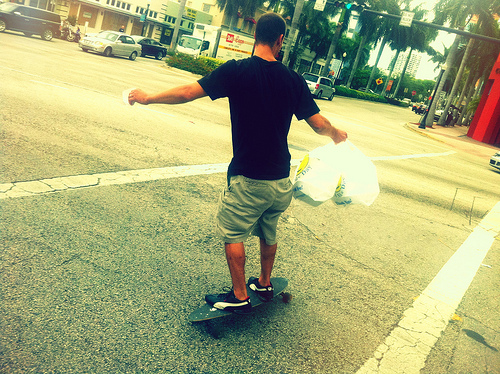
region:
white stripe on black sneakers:
[208, 292, 262, 312]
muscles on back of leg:
[217, 236, 258, 263]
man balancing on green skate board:
[177, 260, 302, 329]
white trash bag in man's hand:
[289, 119, 414, 228]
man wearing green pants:
[201, 158, 297, 257]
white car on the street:
[86, 26, 155, 56]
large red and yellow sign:
[371, 71, 392, 87]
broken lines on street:
[375, 327, 426, 349]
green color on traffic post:
[334, 1, 356, 16]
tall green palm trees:
[331, 5, 396, 117]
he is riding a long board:
[106, 2, 456, 372]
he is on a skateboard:
[96, 4, 428, 361]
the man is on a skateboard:
[96, 7, 443, 369]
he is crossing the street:
[96, 3, 423, 353]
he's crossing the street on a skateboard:
[106, 7, 396, 357]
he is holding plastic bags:
[111, 2, 406, 370]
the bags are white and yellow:
[286, 124, 401, 227]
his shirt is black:
[191, 38, 317, 182]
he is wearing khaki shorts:
[208, 171, 303, 254]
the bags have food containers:
[286, 135, 403, 228]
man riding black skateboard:
[102, 2, 420, 364]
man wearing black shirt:
[172, 47, 324, 174]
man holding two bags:
[285, 126, 387, 222]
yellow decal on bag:
[282, 120, 389, 220]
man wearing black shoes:
[177, 253, 297, 322]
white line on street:
[376, 163, 482, 357]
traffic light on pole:
[314, 0, 497, 75]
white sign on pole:
[345, 4, 495, 61]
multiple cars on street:
[25, 4, 215, 81]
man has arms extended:
[107, 9, 378, 192]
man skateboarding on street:
[126, 12, 381, 336]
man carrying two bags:
[213, 11, 380, 272]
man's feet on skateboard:
[181, 270, 299, 343]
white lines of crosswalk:
[383, 143, 479, 366]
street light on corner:
[417, 58, 451, 135]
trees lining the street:
[291, 9, 485, 126]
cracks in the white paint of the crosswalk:
[1, 167, 109, 204]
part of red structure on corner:
[464, 46, 499, 141]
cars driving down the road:
[1, 8, 169, 60]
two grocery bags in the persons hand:
[292, 130, 384, 206]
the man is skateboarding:
[151, 0, 368, 322]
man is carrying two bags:
[235, 8, 410, 245]